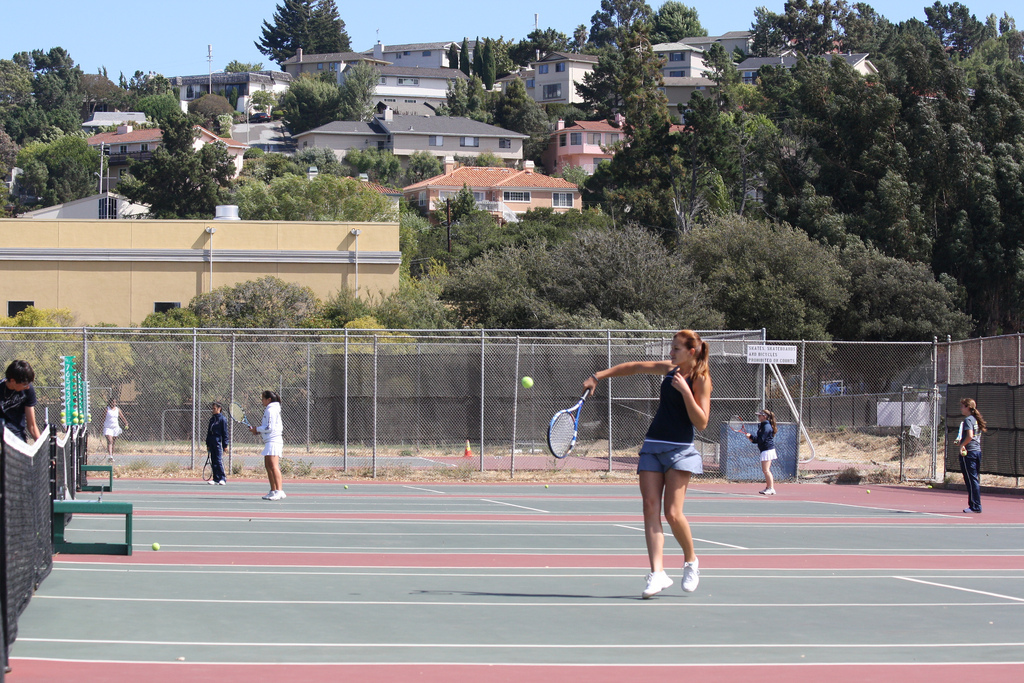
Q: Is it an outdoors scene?
A: Yes, it is outdoors.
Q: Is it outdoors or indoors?
A: It is outdoors.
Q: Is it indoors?
A: No, it is outdoors.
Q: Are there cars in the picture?
A: No, there are no cars.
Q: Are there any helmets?
A: No, there are no helmets.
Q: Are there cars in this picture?
A: No, there are no cars.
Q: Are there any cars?
A: No, there are no cars.